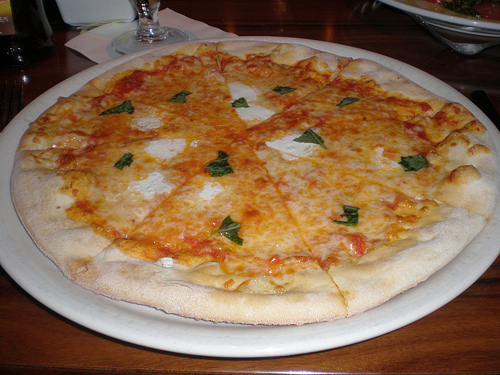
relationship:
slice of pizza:
[259, 141, 484, 294] [6, 31, 495, 336]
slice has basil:
[259, 141, 484, 294] [295, 122, 359, 228]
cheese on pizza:
[98, 66, 425, 258] [6, 31, 495, 336]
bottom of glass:
[111, 29, 191, 58] [116, 1, 184, 51]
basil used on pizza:
[295, 122, 359, 228] [6, 31, 495, 336]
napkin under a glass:
[65, 5, 227, 67] [116, 1, 184, 51]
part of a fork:
[15, 88, 28, 109] [2, 78, 30, 129]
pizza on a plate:
[6, 31, 495, 336] [2, 35, 500, 369]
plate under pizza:
[2, 35, 500, 369] [6, 31, 495, 336]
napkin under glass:
[65, 5, 227, 67] [116, 1, 184, 51]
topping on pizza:
[130, 86, 325, 219] [6, 31, 495, 336]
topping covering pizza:
[8, 36, 500, 326] [6, 31, 495, 336]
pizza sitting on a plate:
[6, 31, 495, 336] [2, 35, 500, 369]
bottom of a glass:
[111, 29, 191, 58] [116, 1, 184, 51]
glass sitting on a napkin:
[116, 1, 184, 51] [65, 5, 227, 67]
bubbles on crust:
[429, 111, 480, 185] [17, 31, 493, 335]